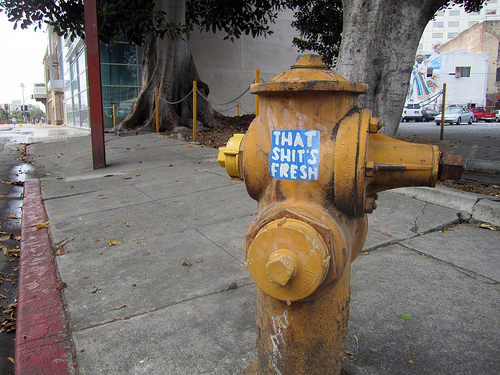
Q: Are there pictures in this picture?
A: No, there are no pictures.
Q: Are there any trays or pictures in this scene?
A: No, there are no pictures or trays.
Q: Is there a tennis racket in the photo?
A: No, there are no rackets.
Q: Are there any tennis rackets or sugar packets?
A: No, there are no tennis rackets or sugar packets.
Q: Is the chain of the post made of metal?
A: Yes, the chain is made of metal.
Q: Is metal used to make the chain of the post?
A: Yes, the chain is made of metal.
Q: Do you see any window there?
A: Yes, there is a window.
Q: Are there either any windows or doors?
A: Yes, there is a window.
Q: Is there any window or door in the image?
A: Yes, there is a window.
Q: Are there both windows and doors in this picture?
A: No, there is a window but no doors.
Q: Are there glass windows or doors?
A: Yes, there is a glass window.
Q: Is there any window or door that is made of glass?
A: Yes, the window is made of glass.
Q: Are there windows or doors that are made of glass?
A: Yes, the window is made of glass.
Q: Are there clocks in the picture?
A: No, there are no clocks.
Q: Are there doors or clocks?
A: No, there are no clocks or doors.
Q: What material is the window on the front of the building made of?
A: The window is made of glass.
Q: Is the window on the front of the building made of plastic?
A: No, the window is made of glass.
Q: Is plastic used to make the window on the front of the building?
A: No, the window is made of glass.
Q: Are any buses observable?
A: No, there are no buses.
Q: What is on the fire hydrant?
A: The sign is on the fire hydrant.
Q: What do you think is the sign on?
A: The sign is on the fire hydrant.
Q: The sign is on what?
A: The sign is on the fire hydrant.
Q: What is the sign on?
A: The sign is on the fire hydrant.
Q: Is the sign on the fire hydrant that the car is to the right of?
A: Yes, the sign is on the hydrant.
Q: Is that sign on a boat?
A: No, the sign is on the hydrant.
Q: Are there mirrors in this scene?
A: No, there are no mirrors.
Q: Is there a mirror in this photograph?
A: No, there are no mirrors.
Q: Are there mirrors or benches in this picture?
A: No, there are no mirrors or benches.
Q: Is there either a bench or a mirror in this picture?
A: No, there are no mirrors or benches.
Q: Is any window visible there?
A: Yes, there is a window.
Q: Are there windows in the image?
A: Yes, there is a window.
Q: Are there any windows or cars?
A: Yes, there is a window.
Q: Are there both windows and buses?
A: No, there is a window but no buses.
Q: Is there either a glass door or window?
A: Yes, there is a glass window.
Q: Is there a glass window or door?
A: Yes, there is a glass window.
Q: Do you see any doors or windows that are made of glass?
A: Yes, the window is made of glass.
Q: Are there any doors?
A: No, there are no doors.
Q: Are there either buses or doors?
A: No, there are no doors or buses.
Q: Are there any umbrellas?
A: No, there are no umbrellas.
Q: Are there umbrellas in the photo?
A: No, there are no umbrellas.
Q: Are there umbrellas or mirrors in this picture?
A: No, there are no umbrellas or mirrors.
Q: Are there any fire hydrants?
A: Yes, there is a fire hydrant.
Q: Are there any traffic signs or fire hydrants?
A: Yes, there is a fire hydrant.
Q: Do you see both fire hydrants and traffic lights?
A: No, there is a fire hydrant but no traffic lights.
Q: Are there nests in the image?
A: No, there are no nests.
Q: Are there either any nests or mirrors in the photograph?
A: No, there are no nests or mirrors.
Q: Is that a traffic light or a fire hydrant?
A: That is a fire hydrant.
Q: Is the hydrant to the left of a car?
A: Yes, the hydrant is to the left of a car.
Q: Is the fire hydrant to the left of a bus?
A: No, the fire hydrant is to the left of a car.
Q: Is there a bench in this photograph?
A: No, there are no benches.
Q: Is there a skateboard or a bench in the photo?
A: No, there are no benches or skateboards.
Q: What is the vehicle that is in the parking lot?
A: The vehicle is a car.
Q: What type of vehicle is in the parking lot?
A: The vehicle is a car.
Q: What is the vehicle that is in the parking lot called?
A: The vehicle is a car.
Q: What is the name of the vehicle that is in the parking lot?
A: The vehicle is a car.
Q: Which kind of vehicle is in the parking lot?
A: The vehicle is a car.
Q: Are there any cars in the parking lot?
A: Yes, there is a car in the parking lot.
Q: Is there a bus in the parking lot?
A: No, there is a car in the parking lot.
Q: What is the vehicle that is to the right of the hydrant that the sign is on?
A: The vehicle is a car.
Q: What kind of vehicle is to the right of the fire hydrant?
A: The vehicle is a car.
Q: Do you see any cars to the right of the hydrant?
A: Yes, there is a car to the right of the hydrant.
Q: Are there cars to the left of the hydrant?
A: No, the car is to the right of the hydrant.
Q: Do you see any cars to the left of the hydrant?
A: No, the car is to the right of the hydrant.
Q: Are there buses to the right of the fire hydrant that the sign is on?
A: No, there is a car to the right of the hydrant.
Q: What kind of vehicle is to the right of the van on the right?
A: The vehicle is a car.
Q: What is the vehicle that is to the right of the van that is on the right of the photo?
A: The vehicle is a car.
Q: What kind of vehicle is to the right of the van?
A: The vehicle is a car.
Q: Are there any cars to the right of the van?
A: Yes, there is a car to the right of the van.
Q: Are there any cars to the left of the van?
A: No, the car is to the right of the van.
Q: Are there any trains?
A: No, there are no trains.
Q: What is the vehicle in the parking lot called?
A: The vehicle is a car.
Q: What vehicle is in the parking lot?
A: The vehicle is a car.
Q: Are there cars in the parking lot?
A: Yes, there is a car in the parking lot.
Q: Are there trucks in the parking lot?
A: No, there is a car in the parking lot.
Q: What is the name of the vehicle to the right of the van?
A: The vehicle is a car.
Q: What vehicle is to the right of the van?
A: The vehicle is a car.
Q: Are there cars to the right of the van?
A: Yes, there is a car to the right of the van.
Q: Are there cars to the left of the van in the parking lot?
A: No, the car is to the right of the van.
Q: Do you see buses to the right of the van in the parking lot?
A: No, there is a car to the right of the van.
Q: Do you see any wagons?
A: No, there are no wagons.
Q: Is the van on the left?
A: No, the van is on the right of the image.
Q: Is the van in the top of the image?
A: Yes, the van is in the top of the image.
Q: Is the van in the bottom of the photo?
A: No, the van is in the top of the image.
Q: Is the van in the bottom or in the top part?
A: The van is in the top of the image.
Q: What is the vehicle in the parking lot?
A: The vehicle is a van.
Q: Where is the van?
A: The van is in the parking lot.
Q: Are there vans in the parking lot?
A: Yes, there is a van in the parking lot.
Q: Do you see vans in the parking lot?
A: Yes, there is a van in the parking lot.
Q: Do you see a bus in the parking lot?
A: No, there is a van in the parking lot.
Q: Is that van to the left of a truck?
A: No, the van is to the left of the car.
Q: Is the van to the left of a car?
A: Yes, the van is to the left of a car.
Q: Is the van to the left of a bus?
A: No, the van is to the left of a car.